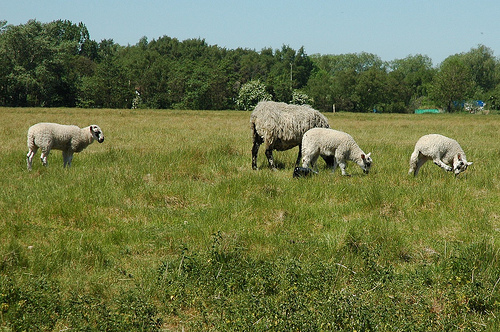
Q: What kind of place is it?
A: It is a pasture.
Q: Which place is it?
A: It is a pasture.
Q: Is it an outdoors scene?
A: Yes, it is outdoors.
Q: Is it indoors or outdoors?
A: It is outdoors.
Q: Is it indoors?
A: No, it is outdoors.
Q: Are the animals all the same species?
A: Yes, all the animals are sheep.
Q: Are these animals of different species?
A: No, all the animals are sheep.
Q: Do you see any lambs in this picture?
A: Yes, there is a lamb.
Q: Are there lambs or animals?
A: Yes, there is a lamb.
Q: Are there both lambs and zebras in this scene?
A: No, there is a lamb but no zebras.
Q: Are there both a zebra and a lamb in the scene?
A: No, there is a lamb but no zebras.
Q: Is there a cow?
A: No, there are no cows.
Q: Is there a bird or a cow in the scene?
A: No, there are no cows or birds.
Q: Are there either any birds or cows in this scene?
A: No, there are no cows or birds.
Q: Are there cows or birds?
A: No, there are no cows or birds.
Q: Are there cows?
A: No, there are no cows.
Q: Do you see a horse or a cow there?
A: No, there are no cows or horses.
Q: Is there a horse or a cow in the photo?
A: No, there are no cows or horses.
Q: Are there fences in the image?
A: Yes, there is a fence.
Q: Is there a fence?
A: Yes, there is a fence.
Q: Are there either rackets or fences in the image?
A: Yes, there is a fence.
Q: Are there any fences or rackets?
A: Yes, there is a fence.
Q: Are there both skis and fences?
A: No, there is a fence but no skis.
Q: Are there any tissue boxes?
A: No, there are no tissue boxes.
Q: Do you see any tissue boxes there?
A: No, there are no tissue boxes.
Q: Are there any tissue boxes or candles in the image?
A: No, there are no tissue boxes or candles.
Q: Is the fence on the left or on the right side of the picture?
A: The fence is on the right of the image.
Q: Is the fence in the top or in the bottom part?
A: The fence is in the top of the image.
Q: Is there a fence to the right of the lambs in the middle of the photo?
A: Yes, there is a fence to the right of the lambs.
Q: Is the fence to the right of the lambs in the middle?
A: Yes, the fence is to the right of the lambs.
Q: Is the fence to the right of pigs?
A: No, the fence is to the right of the lambs.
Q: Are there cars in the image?
A: No, there are no cars.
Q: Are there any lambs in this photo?
A: Yes, there are lambs.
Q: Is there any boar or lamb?
A: Yes, there are lambs.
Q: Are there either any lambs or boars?
A: Yes, there are lambs.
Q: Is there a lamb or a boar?
A: Yes, there are lambs.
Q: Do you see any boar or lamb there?
A: Yes, there are lambs.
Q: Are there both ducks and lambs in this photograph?
A: No, there are lambs but no ducks.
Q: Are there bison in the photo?
A: No, there are no bison.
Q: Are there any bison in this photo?
A: No, there are no bison.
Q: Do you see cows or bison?
A: No, there are no bison or cows.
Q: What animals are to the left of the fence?
A: The animals are lambs.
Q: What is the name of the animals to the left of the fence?
A: The animals are lambs.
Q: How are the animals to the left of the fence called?
A: The animals are lambs.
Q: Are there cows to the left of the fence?
A: No, there are lambs to the left of the fence.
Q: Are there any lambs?
A: Yes, there is a lamb.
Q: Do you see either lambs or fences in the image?
A: Yes, there is a lamb.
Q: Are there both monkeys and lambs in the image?
A: No, there is a lamb but no monkeys.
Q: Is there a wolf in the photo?
A: No, there are no wolves.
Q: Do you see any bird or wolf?
A: No, there are no wolves or birds.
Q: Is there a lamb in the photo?
A: Yes, there is a lamb.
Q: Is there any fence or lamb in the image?
A: Yes, there is a lamb.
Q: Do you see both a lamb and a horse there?
A: No, there is a lamb but no horses.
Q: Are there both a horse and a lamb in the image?
A: No, there is a lamb but no horses.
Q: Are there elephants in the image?
A: No, there are no elephants.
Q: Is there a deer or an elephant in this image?
A: No, there are no elephants or deer.